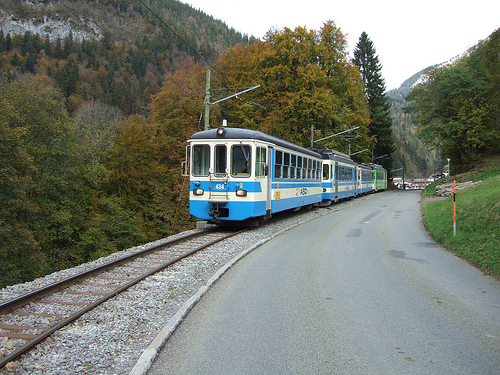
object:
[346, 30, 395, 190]
tree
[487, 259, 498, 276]
grass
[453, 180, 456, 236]
pole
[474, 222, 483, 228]
grass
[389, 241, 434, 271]
ground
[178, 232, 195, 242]
tracks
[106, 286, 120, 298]
tracks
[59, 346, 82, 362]
gravel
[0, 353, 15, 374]
track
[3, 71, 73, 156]
tree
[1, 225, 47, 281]
tree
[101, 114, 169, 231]
tree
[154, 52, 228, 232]
tree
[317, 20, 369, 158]
tree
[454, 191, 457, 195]
orange black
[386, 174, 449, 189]
town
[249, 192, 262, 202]
stripes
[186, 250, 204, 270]
gravel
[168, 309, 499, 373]
road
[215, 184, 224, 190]
number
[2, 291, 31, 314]
tracks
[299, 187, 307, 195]
writing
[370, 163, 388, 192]
car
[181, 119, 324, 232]
train car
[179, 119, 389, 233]
train